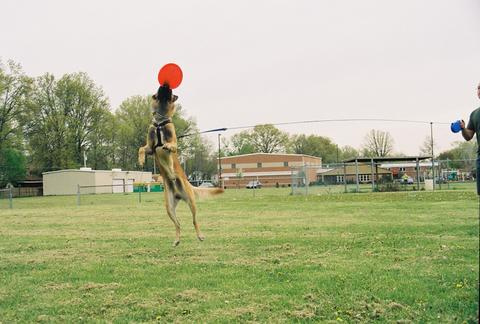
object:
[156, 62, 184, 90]
frisbee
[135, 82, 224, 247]
dog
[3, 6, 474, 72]
clouds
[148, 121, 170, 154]
harness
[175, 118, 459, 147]
leash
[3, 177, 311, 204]
fence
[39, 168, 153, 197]
building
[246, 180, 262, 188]
car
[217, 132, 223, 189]
pole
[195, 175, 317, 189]
parking lot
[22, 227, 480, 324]
grass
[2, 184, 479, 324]
area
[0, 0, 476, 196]
air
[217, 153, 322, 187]
building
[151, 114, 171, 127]
collar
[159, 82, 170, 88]
mouth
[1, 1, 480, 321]
photo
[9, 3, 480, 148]
day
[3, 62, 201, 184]
trees